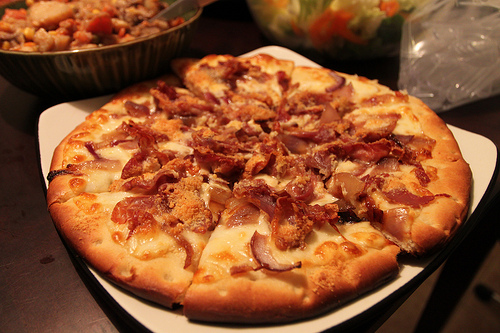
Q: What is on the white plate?
A: Pizza.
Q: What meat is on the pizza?
A: Bacon.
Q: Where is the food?
A: On a black table.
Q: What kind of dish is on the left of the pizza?
A: Silver bowl.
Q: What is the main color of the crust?
A: Brown.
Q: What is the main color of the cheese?
A: White.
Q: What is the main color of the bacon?
A: Red.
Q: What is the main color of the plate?
A: White.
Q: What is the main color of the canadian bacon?
A: Red.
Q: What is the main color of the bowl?
A: Silver.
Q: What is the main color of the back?
A: Clear.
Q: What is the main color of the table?
A: Brown.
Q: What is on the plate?
A: Pizza.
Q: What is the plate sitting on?
A: White.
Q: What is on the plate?
A: Pizza.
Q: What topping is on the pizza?
A: Bacon.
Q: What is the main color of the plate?
A: White.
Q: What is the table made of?
A: Wood.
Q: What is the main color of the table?
A: Brown.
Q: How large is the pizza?
A: LArge.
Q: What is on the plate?
A: Pizza.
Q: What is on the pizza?
A: Bacon.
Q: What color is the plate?
A: White.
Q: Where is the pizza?
A: Table.